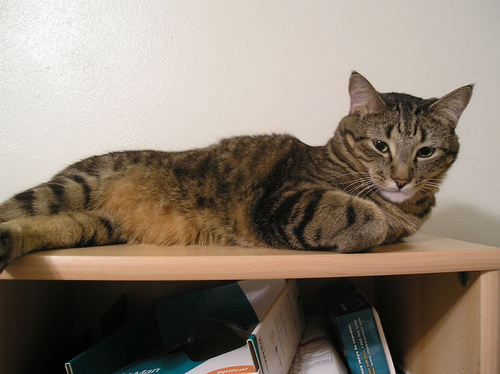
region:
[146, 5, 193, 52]
this is the wall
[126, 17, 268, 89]
the wall is white in color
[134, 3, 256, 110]
the wall is clean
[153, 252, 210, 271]
this is a shelf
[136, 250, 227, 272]
the shelf is wooden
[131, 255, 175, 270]
the shelf is brown in color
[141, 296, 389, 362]
these are some boxes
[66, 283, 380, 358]
the boxes are small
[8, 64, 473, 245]
this is a cat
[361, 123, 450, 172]
these are the eyes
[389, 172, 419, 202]
Cat has pink nose.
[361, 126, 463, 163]
Cat has golden colored eyes.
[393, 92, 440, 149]
Cat has dark stripes on head.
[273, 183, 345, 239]
Cat has dark stripes on leg.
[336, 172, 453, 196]
Cat has white whiskers.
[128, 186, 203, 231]
Cat has tan tummy.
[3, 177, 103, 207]
Cat has dark stripes on back leg.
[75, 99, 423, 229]
Cat sitting on top of shelving unit.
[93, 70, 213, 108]
White wall behind cat.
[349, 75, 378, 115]
White hair inside of cat's ear.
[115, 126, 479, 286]
This is a cat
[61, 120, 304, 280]
The cat is laying down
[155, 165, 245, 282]
This is a stomach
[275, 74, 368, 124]
This is an ear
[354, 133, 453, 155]
These are two eyes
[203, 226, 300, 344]
This is a bookcase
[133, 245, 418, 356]
The bookcase is wooden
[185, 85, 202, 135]
The wall is white wood and empty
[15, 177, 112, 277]
These are two legs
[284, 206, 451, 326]
This is a paw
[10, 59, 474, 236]
the cat is lying down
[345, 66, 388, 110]
this is the ear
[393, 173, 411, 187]
this is the nose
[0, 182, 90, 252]
these are the rare legs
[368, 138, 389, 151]
this is the eye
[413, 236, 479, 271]
this is a stand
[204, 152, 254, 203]
the cat is grey in color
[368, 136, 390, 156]
the eye is open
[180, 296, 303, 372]
this is a box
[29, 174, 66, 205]
Patch of hair of cat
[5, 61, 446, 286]
Large cat sitting on shelf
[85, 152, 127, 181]
Patch of hair of cat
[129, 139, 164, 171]
Patch of hair of cat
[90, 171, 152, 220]
Patch of hair of cat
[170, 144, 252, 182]
Patch of hair of cat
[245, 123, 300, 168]
Patch of hair of cat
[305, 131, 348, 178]
Patch of hair of cat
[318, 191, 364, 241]
Patch of hair of cat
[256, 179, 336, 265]
Patch of hair of cat